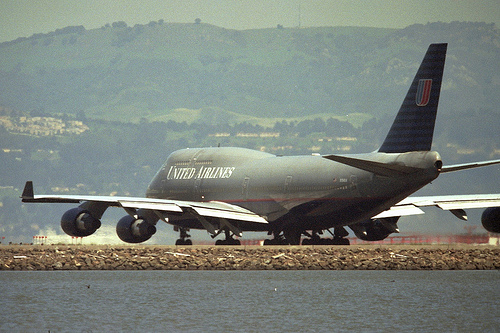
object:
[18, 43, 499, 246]
747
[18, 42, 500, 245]
airplane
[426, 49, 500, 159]
ground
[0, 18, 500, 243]
vegetation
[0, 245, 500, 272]
shore line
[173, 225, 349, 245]
landing gear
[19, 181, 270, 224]
wing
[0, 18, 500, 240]
mountains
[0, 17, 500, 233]
tree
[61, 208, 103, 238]
engine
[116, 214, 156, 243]
engine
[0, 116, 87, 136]
town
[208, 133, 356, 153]
town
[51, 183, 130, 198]
town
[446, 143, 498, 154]
town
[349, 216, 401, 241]
engine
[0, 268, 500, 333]
water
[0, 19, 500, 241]
hills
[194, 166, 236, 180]
lettering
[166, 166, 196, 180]
lettering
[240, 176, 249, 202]
door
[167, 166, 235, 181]
sticker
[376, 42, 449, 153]
stabilizer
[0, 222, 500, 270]
airport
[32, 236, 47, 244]
light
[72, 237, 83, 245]
light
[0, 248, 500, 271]
rock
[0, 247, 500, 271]
groups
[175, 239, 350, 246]
wheels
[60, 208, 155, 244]
gear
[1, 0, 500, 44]
sky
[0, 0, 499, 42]
horizon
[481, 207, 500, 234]
engine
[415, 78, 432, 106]
logo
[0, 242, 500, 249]
runway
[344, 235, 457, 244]
fence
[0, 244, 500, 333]
surface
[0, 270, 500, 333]
ripples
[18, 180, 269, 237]
left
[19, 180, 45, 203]
bend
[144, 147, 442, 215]
gray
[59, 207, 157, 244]
two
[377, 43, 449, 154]
vertical